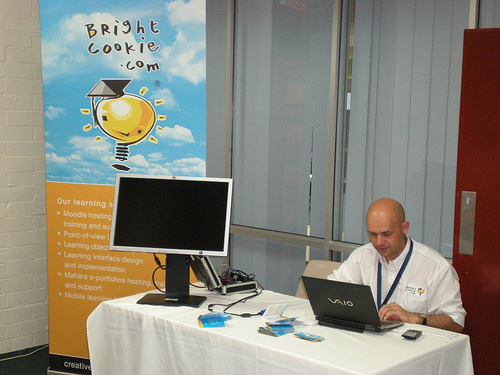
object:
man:
[316, 193, 474, 339]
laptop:
[296, 272, 407, 335]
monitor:
[104, 167, 234, 260]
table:
[79, 276, 481, 375]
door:
[450, 27, 500, 374]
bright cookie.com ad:
[38, 0, 212, 375]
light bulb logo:
[81, 89, 162, 174]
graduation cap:
[84, 76, 133, 99]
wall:
[1, 2, 50, 353]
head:
[363, 195, 411, 258]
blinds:
[223, 0, 471, 309]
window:
[218, 0, 469, 311]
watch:
[418, 311, 430, 326]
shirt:
[324, 239, 465, 327]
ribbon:
[372, 238, 415, 317]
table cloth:
[84, 273, 479, 375]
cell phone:
[401, 328, 423, 340]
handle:
[457, 189, 480, 258]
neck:
[374, 236, 411, 263]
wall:
[206, 3, 494, 327]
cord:
[148, 258, 217, 297]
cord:
[207, 268, 267, 323]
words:
[55, 197, 71, 207]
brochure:
[262, 303, 293, 325]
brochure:
[195, 309, 228, 329]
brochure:
[263, 318, 297, 331]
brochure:
[294, 331, 329, 343]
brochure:
[258, 325, 295, 337]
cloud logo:
[160, 0, 211, 88]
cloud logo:
[156, 121, 195, 143]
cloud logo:
[47, 135, 118, 172]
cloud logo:
[55, 11, 157, 78]